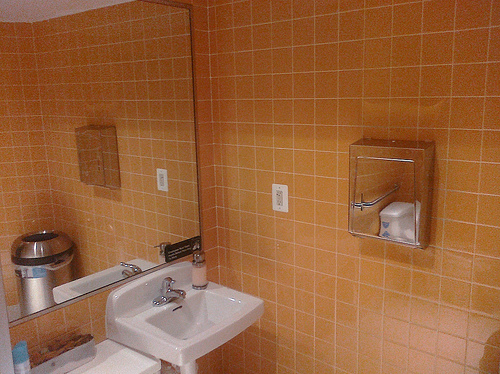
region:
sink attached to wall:
[79, 251, 263, 368]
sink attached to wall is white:
[68, 239, 261, 372]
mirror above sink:
[8, 5, 247, 306]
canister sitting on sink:
[172, 227, 215, 292]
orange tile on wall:
[227, 104, 436, 349]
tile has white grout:
[272, 258, 447, 363]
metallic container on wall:
[307, 115, 459, 260]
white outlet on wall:
[262, 171, 302, 225]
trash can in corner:
[5, 201, 97, 338]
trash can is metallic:
[5, 205, 85, 333]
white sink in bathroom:
[117, 250, 248, 360]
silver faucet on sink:
[160, 278, 187, 303]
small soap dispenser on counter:
[190, 248, 205, 292]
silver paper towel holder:
[338, 128, 445, 248]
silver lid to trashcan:
[11, 228, 73, 259]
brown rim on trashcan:
[2, 250, 66, 270]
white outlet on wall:
[265, 180, 289, 215]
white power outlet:
[262, 183, 290, 214]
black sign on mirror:
[160, 228, 208, 263]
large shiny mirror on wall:
[0, 10, 200, 316]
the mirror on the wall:
[0, 0, 205, 283]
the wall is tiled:
[217, 12, 469, 143]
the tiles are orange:
[234, 16, 426, 97]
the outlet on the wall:
[270, 180, 290, 213]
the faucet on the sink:
[150, 275, 184, 301]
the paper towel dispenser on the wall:
[340, 128, 448, 263]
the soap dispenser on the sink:
[182, 248, 227, 286]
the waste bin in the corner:
[0, 228, 85, 285]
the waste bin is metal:
[4, 225, 76, 280]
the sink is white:
[112, 280, 267, 361]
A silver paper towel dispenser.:
[342, 129, 438, 251]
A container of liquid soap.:
[190, 245, 207, 287]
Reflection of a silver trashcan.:
[8, 223, 75, 317]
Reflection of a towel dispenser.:
[70, 118, 126, 190]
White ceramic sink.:
[101, 250, 263, 372]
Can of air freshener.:
[12, 336, 32, 371]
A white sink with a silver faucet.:
[105, 257, 266, 372]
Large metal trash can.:
[7, 224, 79, 316]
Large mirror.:
[0, 0, 204, 325]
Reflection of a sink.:
[50, 253, 155, 303]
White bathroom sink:
[102, 246, 283, 368]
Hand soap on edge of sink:
[181, 236, 215, 293]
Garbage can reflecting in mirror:
[3, 231, 83, 308]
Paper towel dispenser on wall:
[330, 123, 450, 258]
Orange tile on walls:
[302, 248, 423, 358]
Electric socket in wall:
[261, 173, 296, 221]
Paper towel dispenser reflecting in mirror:
[59, 123, 133, 193]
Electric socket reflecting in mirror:
[151, 166, 173, 197]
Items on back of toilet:
[5, 338, 112, 370]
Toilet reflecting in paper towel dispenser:
[374, 194, 422, 246]